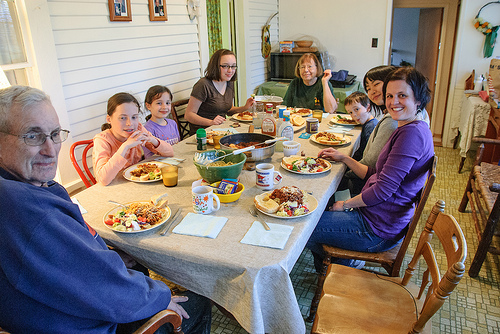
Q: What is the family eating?
A: Salad.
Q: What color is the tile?
A: Brown.